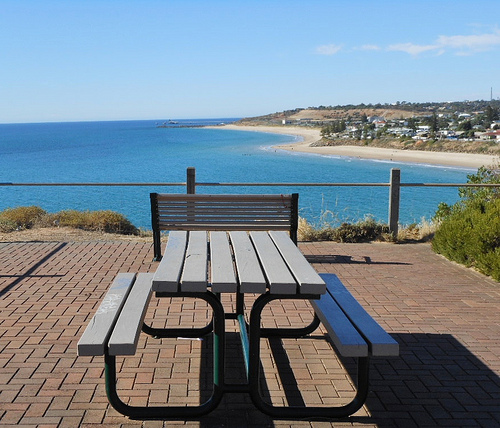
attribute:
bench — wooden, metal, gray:
[147, 189, 301, 256]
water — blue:
[0, 117, 499, 235]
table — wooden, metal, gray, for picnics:
[76, 229, 399, 423]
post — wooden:
[181, 166, 204, 228]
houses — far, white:
[278, 99, 498, 148]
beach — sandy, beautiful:
[208, 121, 499, 176]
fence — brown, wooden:
[2, 165, 499, 235]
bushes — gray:
[293, 208, 448, 251]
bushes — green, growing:
[429, 164, 498, 289]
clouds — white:
[308, 20, 499, 67]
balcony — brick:
[2, 230, 499, 425]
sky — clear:
[2, 2, 499, 122]